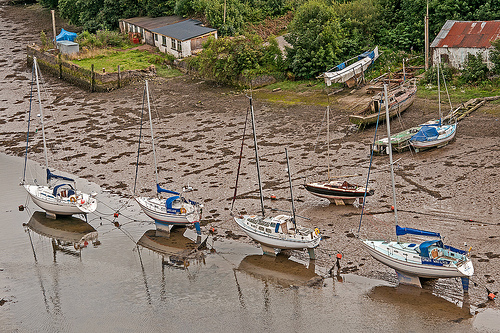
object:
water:
[0, 152, 499, 332]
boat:
[300, 105, 376, 205]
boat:
[348, 77, 418, 127]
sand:
[0, 4, 496, 307]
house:
[429, 18, 499, 83]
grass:
[71, 49, 185, 78]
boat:
[316, 44, 382, 87]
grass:
[253, 91, 337, 108]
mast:
[245, 81, 266, 218]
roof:
[428, 18, 499, 49]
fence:
[25, 42, 156, 92]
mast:
[381, 78, 402, 243]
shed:
[147, 22, 219, 62]